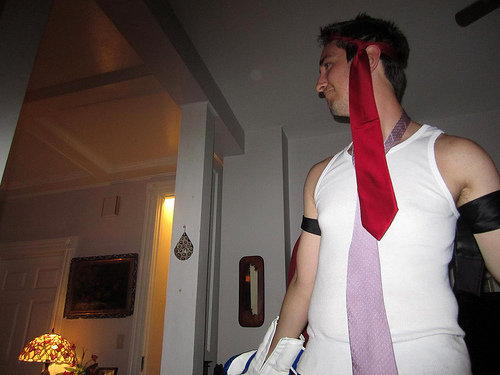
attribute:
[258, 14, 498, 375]
man — smiling, indoors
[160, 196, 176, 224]
light — on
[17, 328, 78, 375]
lamp — beautiful, mulitcolored, on, tiffany, yellow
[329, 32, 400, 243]
tie — lavender, red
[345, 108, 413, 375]
necktie — purple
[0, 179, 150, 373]
wall — white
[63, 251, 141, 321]
painting — wooden, black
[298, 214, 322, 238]
armband — black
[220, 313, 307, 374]
glove — untied, white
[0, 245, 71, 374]
door — white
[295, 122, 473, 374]
shirt — white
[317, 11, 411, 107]
hair — dark, short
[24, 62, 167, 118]
trim — white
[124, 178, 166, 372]
edge — white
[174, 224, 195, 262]
hanging — art, spotted, black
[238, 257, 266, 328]
object — brown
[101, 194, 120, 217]
square — white